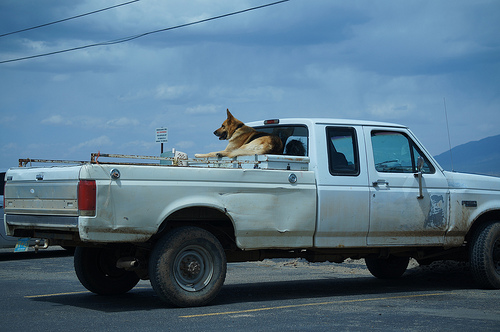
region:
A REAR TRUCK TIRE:
[143, 220, 231, 310]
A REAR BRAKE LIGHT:
[74, 172, 99, 218]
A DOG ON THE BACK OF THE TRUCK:
[189, 104, 286, 161]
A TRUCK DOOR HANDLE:
[369, 176, 394, 191]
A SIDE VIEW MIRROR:
[409, 151, 429, 182]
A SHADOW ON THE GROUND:
[24, 267, 489, 317]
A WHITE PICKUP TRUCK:
[1, 112, 498, 312]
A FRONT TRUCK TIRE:
[462, 212, 498, 292]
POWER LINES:
[1, 2, 193, 65]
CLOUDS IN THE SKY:
[59, 7, 217, 107]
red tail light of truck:
[58, 173, 108, 235]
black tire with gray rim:
[158, 230, 226, 323]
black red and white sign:
[150, 119, 171, 139]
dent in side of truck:
[207, 190, 303, 273]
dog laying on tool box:
[152, 97, 256, 192]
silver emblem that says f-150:
[427, 192, 486, 226]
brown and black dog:
[141, 101, 281, 191]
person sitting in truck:
[274, 126, 314, 166]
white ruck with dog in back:
[15, 104, 476, 321]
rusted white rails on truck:
[11, 141, 208, 189]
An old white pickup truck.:
[2, 117, 499, 297]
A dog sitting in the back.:
[198, 113, 282, 160]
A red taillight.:
[76, 178, 96, 218]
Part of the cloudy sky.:
[162, 40, 325, 90]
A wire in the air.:
[62, 32, 167, 54]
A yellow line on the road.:
[171, 302, 307, 320]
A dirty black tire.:
[148, 226, 228, 306]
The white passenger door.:
[363, 125, 451, 248]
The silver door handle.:
[370, 177, 390, 189]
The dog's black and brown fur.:
[240, 130, 265, 146]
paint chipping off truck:
[410, 182, 454, 236]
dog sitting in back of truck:
[187, 108, 283, 178]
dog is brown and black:
[176, 89, 290, 181]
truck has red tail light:
[67, 169, 107, 231]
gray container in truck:
[177, 140, 309, 182]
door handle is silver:
[370, 168, 393, 195]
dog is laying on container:
[182, 106, 287, 173]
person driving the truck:
[275, 133, 317, 165]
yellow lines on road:
[22, 248, 493, 329]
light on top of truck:
[257, 111, 286, 139]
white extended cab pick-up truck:
[2, 118, 497, 308]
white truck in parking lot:
[2, 118, 498, 303]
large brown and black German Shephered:
[192, 106, 274, 159]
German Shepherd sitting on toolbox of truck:
[186, 110, 309, 169]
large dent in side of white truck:
[270, 186, 308, 233]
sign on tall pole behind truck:
[153, 125, 168, 152]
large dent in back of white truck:
[100, 185, 121, 229]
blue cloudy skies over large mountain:
[1, 0, 498, 177]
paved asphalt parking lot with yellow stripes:
[0, 243, 498, 330]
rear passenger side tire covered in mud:
[150, 224, 225, 307]